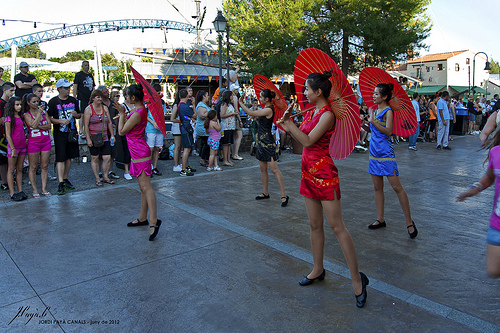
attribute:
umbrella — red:
[129, 61, 168, 140]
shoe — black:
[148, 216, 163, 242]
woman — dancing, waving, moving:
[279, 70, 373, 312]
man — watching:
[46, 76, 83, 197]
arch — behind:
[1, 17, 216, 58]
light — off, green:
[210, 9, 230, 34]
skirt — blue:
[367, 105, 401, 177]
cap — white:
[53, 77, 75, 90]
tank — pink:
[26, 107, 53, 144]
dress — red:
[300, 102, 343, 201]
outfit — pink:
[122, 105, 154, 177]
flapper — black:
[249, 104, 278, 162]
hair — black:
[305, 67, 332, 102]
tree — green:
[221, 0, 434, 80]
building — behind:
[388, 48, 490, 88]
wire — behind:
[1, 16, 495, 73]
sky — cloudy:
[0, 0, 243, 56]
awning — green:
[409, 84, 448, 93]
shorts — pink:
[29, 138, 54, 153]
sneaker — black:
[57, 178, 66, 195]